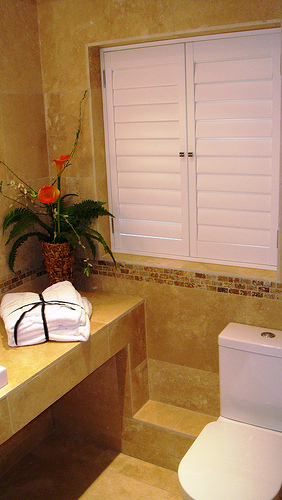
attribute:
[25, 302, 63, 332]
towel — white 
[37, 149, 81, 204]
flowers — orange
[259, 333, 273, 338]
button — gray, metal, push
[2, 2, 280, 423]
wall — tiled , brown 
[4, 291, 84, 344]
black ribbon — black 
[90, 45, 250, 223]
window — closed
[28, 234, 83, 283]
planter — stone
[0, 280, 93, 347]
clothes — white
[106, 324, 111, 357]
grout line — white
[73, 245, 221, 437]
tiles — yellow, stone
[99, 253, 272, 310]
tiles — small, colored, trim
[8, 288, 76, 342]
ribbon — black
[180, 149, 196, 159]
handles — brown, metal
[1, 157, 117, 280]
plant — green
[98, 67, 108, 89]
hinge — gray 